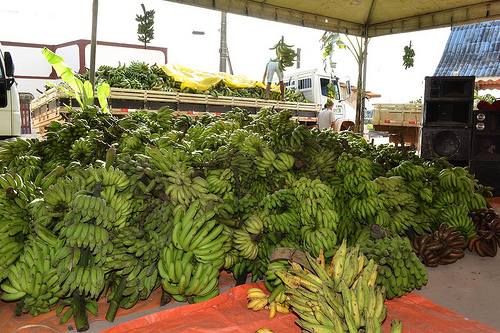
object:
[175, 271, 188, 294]
banana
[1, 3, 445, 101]
sky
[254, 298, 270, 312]
banana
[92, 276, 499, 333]
sheet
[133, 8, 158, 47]
banana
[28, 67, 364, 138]
truck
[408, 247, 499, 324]
ground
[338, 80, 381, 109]
shed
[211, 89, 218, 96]
banana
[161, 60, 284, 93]
cover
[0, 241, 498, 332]
floor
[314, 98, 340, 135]
person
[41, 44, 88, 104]
leaf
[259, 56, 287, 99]
person